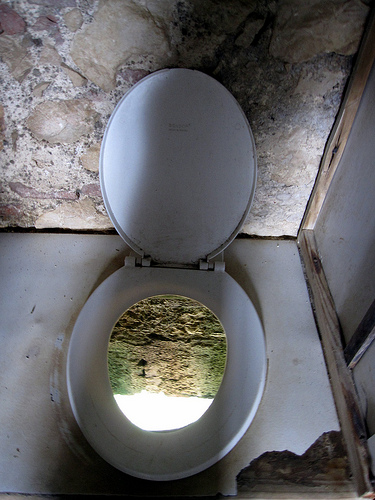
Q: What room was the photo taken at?
A: It was taken at the bathroom.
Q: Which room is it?
A: It is a bathroom.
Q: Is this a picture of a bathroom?
A: Yes, it is showing a bathroom.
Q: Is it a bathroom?
A: Yes, it is a bathroom.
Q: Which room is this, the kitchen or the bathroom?
A: It is the bathroom.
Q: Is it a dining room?
A: No, it is a bathroom.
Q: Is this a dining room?
A: No, it is a bathroom.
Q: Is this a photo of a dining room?
A: No, the picture is showing a bathroom.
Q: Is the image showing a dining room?
A: No, the picture is showing a bathroom.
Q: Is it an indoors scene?
A: Yes, it is indoors.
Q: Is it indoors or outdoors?
A: It is indoors.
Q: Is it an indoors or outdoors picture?
A: It is indoors.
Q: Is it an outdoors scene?
A: No, it is indoors.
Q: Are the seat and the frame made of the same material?
A: No, the seat is made of plastic and the frame is made of wood.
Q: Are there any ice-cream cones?
A: No, there are no ice-cream cones.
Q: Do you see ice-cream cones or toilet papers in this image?
A: No, there are no ice-cream cones or toilet papers.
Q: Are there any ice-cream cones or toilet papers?
A: No, there are no ice-cream cones or toilet papers.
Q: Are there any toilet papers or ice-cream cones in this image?
A: No, there are no ice-cream cones or toilet papers.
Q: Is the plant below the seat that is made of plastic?
A: Yes, the plant is below the seat.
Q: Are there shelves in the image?
A: No, there are no shelves.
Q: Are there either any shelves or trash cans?
A: No, there are no shelves or trash cans.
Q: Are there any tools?
A: No, there are no tools.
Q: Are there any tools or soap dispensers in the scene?
A: No, there are no tools or soap dispensers.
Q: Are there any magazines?
A: No, there are no magazines.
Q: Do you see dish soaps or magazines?
A: No, there are no magazines or dish soaps.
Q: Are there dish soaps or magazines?
A: No, there are no magazines or dish soaps.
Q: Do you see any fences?
A: No, there are no fences.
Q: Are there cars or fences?
A: No, there are no fences or cars.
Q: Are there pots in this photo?
A: No, there are no pots.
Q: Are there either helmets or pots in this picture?
A: No, there are no pots or helmets.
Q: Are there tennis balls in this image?
A: No, there are no tennis balls.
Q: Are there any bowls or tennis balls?
A: No, there are no tennis balls or bowls.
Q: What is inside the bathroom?
A: The toilet is inside the bathroom.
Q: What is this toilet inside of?
A: The toilet is inside the bathroom.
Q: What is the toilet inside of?
A: The toilet is inside the bathroom.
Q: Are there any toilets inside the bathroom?
A: Yes, there is a toilet inside the bathroom.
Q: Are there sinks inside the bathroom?
A: No, there is a toilet inside the bathroom.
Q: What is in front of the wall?
A: The toilet is in front of the wall.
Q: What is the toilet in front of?
A: The toilet is in front of the wall.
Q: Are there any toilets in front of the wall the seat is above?
A: Yes, there is a toilet in front of the wall.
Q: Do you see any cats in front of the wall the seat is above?
A: No, there is a toilet in front of the wall.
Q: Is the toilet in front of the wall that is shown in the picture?
A: Yes, the toilet is in front of the wall.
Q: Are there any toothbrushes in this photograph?
A: No, there are no toothbrushes.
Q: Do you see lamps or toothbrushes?
A: No, there are no toothbrushes or lamps.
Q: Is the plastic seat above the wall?
A: Yes, the seat is above the wall.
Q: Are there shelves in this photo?
A: No, there are no shelves.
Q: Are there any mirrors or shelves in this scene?
A: No, there are no shelves or mirrors.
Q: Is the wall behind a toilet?
A: Yes, the wall is behind a toilet.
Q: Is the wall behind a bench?
A: No, the wall is behind a toilet.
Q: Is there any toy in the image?
A: No, there are no toys.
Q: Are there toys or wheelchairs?
A: No, there are no toys or wheelchairs.